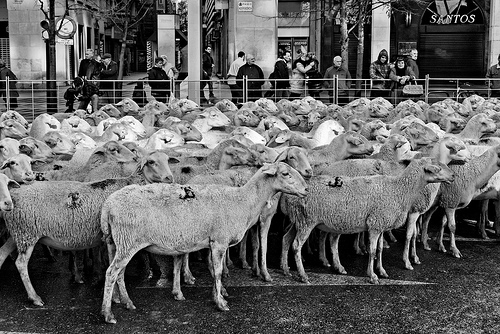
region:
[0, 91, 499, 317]
a herd of goats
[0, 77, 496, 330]
goats behind a fence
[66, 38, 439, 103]
group of people standing on the other side of the fence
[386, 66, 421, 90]
arms resting on the fence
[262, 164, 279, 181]
floppy ear on the side of the head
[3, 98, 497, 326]
goats standing on the dirt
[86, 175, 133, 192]
black spot on the goat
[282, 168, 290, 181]
small black eye on the side of the goat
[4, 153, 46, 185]
head turned to the side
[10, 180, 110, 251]
fluffy hair on the body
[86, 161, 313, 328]
sheep standing in a group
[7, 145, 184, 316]
sheep standing in a group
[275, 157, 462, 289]
sheep standing in a group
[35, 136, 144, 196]
sheep standing in a group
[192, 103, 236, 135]
sheep standing in a group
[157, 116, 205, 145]
sheep standing in a group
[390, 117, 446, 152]
sheep standing in a group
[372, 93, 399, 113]
sheep standing in a group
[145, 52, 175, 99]
person standing behind some sheep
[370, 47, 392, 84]
person standing behind some sheep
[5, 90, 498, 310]
herd of sheep standing around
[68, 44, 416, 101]
people watching the sheep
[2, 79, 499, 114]
fence between people and sheep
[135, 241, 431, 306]
white arrow painted on floor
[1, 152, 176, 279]
sheep looking towards camera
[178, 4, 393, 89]
pillars behind fence line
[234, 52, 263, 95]
man wearing black jacket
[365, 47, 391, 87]
person wearing jacket with hood up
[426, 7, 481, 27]
white santos sign in background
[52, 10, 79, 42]
clock in the background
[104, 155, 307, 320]
a standing white sheep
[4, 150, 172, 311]
a standing white sheep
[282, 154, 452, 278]
a standing white sheep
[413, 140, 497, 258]
a standing white sheep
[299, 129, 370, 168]
a standing white sheep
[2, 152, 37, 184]
a standing white sheep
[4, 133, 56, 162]
a standing white sheep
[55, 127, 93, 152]
a standing white sheep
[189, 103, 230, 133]
a standing white sheep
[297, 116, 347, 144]
a standing white sheep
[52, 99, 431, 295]
Sheep standing in large pen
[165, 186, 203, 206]
Black tag on a sheep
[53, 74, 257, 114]
Metal fence behind sheep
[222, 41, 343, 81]
People looking at sheep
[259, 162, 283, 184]
Ear on a sheep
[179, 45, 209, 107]
Support pillar of a building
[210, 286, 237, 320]
Hooves of a sheep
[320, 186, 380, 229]
Fur on a sheep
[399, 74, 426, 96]
Purse of a woman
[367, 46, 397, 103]
Person wearing a jacket with a hood